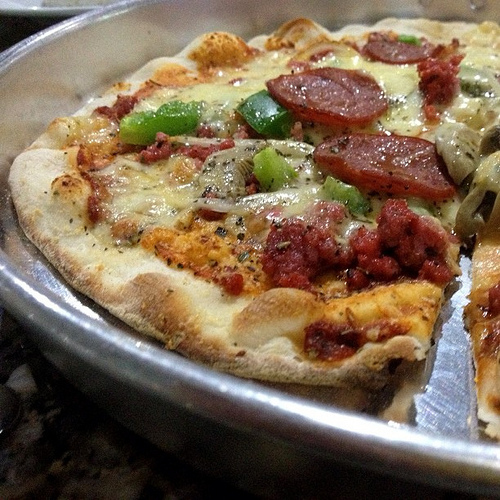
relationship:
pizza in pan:
[11, 20, 499, 405] [2, 1, 500, 498]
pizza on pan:
[11, 20, 499, 405] [2, 1, 500, 498]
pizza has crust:
[11, 20, 499, 405] [9, 121, 428, 386]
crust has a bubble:
[9, 121, 428, 386] [229, 284, 326, 355]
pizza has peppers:
[11, 20, 499, 405] [112, 95, 205, 153]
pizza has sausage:
[11, 20, 499, 405] [311, 131, 455, 202]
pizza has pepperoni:
[11, 20, 499, 405] [264, 64, 389, 128]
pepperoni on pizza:
[264, 64, 389, 128] [11, 20, 499, 405]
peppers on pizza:
[112, 95, 205, 153] [11, 20, 499, 405]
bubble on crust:
[229, 284, 326, 355] [9, 121, 428, 386]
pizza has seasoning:
[11, 20, 499, 405] [183, 157, 254, 272]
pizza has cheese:
[11, 20, 499, 405] [85, 33, 496, 274]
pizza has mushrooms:
[11, 20, 499, 405] [199, 148, 255, 199]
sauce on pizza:
[263, 197, 451, 285] [11, 20, 499, 405]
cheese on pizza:
[85, 33, 496, 274] [11, 20, 499, 405]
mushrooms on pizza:
[199, 148, 255, 199] [11, 20, 499, 405]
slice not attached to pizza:
[461, 204, 499, 438] [11, 20, 499, 405]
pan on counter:
[2, 1, 500, 498] [2, 311, 265, 495]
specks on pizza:
[183, 157, 254, 272] [11, 20, 499, 405]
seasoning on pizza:
[183, 157, 254, 272] [11, 20, 499, 405]